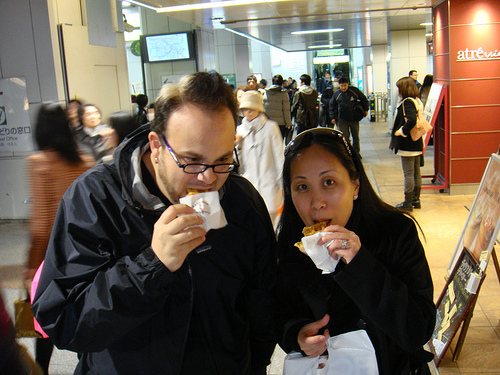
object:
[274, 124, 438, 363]
woman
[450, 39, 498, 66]
sign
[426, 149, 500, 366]
sign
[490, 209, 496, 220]
drinks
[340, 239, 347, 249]
ring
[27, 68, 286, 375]
man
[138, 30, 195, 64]
television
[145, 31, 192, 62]
map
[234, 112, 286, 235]
coat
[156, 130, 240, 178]
eyeglasses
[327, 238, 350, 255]
finger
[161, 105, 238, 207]
face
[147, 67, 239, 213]
head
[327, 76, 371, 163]
people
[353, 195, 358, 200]
earring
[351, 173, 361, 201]
ear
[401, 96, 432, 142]
purse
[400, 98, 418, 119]
shoulder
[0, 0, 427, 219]
wall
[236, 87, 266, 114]
hat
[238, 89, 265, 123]
head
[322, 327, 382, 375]
bag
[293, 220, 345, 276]
food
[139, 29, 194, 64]
monitor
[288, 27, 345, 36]
lights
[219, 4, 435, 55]
ceiling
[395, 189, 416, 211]
boots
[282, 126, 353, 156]
sunglasses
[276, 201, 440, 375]
jacket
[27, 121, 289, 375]
jacket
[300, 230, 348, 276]
tissue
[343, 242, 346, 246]
part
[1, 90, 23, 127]
part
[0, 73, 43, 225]
portrait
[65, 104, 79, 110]
spectacle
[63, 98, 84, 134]
man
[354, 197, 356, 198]
part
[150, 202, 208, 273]
hand